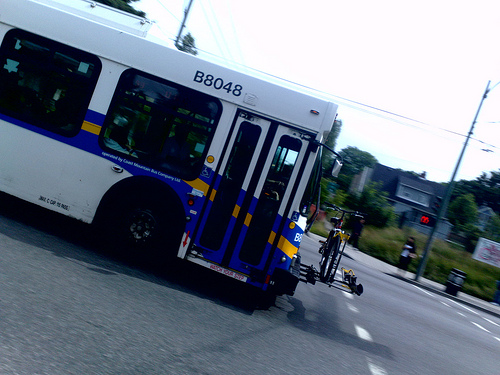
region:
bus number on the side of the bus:
[183, 67, 253, 102]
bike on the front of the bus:
[316, 204, 353, 287]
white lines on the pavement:
[343, 300, 371, 373]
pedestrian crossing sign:
[413, 210, 434, 230]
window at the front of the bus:
[99, 70, 206, 166]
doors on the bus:
[217, 105, 275, 282]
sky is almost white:
[286, 37, 410, 64]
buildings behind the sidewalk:
[350, 159, 422, 224]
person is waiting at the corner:
[394, 234, 419, 276]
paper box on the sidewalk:
[445, 262, 465, 296]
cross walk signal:
[412, 206, 441, 233]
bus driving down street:
[3, 3, 377, 319]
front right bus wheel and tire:
[83, 168, 193, 275]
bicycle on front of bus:
[310, 194, 371, 292]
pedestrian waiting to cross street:
[389, 229, 426, 281]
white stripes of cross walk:
[317, 245, 499, 371]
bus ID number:
[182, 61, 247, 101]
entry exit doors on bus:
[171, 100, 323, 322]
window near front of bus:
[90, 54, 230, 192]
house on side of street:
[350, 155, 498, 263]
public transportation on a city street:
[10, 5, 498, 278]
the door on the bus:
[197, 94, 295, 305]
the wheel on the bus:
[100, 160, 199, 264]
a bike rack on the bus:
[315, 194, 407, 297]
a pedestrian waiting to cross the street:
[391, 233, 446, 279]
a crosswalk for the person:
[323, 240, 499, 360]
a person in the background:
[345, 205, 375, 253]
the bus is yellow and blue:
[162, 157, 314, 281]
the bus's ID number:
[168, 60, 248, 105]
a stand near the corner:
[435, 260, 472, 302]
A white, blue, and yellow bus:
[0, 1, 361, 302]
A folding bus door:
[189, 107, 317, 288]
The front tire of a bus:
[99, 182, 181, 274]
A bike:
[319, 200, 368, 285]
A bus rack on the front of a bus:
[297, 257, 364, 302]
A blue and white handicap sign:
[199, 163, 211, 179]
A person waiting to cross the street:
[396, 235, 421, 277]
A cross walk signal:
[418, 210, 433, 227]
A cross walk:
[329, 246, 499, 374]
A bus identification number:
[189, 63, 248, 99]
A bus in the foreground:
[3, 0, 378, 325]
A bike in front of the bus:
[1, 1, 391, 326]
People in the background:
[346, 199, 424, 284]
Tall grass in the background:
[333, 185, 498, 309]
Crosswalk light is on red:
[414, 203, 439, 245]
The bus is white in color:
[1, 2, 390, 321]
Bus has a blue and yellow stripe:
[0, 106, 309, 290]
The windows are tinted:
[1, 22, 314, 297]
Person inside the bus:
[152, 113, 222, 190]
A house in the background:
[352, 146, 462, 251]